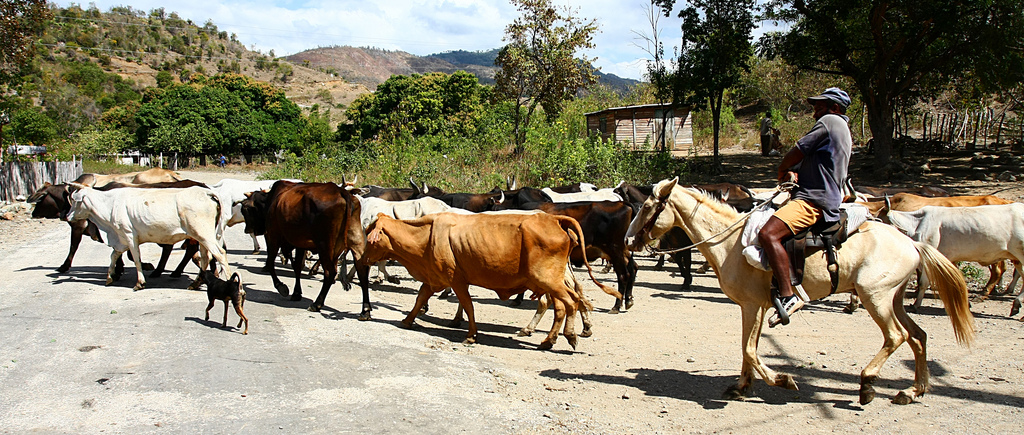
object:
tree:
[116, 88, 193, 165]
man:
[762, 80, 855, 322]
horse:
[622, 173, 975, 402]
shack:
[591, 95, 701, 156]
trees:
[625, 2, 681, 180]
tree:
[340, 67, 500, 155]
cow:
[57, 183, 241, 287]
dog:
[187, 268, 256, 333]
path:
[11, 170, 562, 432]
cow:
[361, 195, 448, 286]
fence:
[895, 114, 1016, 145]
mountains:
[2, 4, 338, 160]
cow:
[877, 202, 1022, 312]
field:
[2, 153, 1018, 426]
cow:
[65, 166, 180, 183]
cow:
[360, 185, 422, 198]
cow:
[247, 181, 368, 318]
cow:
[428, 181, 532, 212]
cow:
[223, 189, 261, 228]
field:
[175, 218, 715, 435]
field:
[373, 216, 1020, 430]